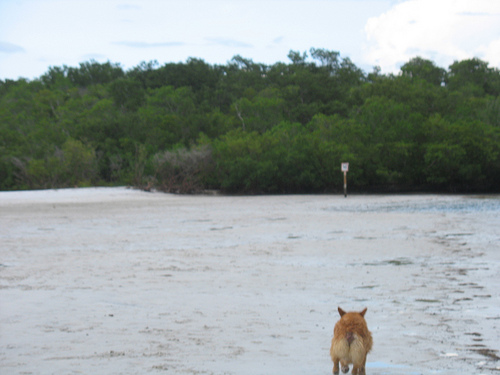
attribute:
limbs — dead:
[127, 152, 217, 190]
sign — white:
[337, 159, 352, 199]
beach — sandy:
[9, 189, 494, 363]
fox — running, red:
[332, 304, 372, 374]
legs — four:
[330, 357, 369, 374]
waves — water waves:
[9, 199, 499, 367]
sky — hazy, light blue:
[8, 6, 495, 91]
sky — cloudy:
[0, 0, 499, 84]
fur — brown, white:
[339, 323, 364, 359]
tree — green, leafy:
[95, 77, 176, 187]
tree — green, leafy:
[170, 65, 260, 187]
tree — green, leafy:
[260, 57, 343, 196]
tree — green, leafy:
[324, 75, 456, 195]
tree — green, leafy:
[401, 56, 497, 191]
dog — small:
[324, 303, 376, 373]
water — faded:
[1, 193, 498, 373]